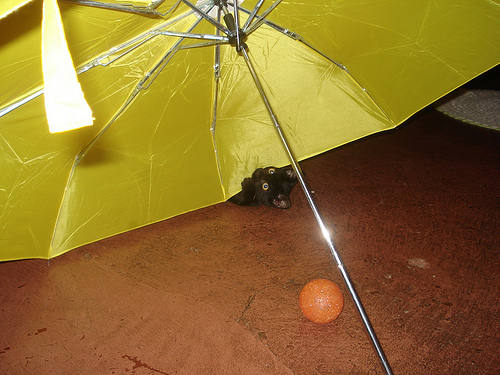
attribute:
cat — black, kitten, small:
[232, 162, 305, 211]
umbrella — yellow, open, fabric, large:
[1, 1, 499, 264]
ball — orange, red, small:
[294, 274, 348, 326]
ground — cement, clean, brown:
[4, 113, 500, 373]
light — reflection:
[312, 216, 345, 250]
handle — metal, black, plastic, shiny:
[242, 43, 389, 371]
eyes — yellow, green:
[264, 160, 278, 196]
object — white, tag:
[33, 1, 102, 136]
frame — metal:
[1, 7, 362, 148]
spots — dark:
[4, 320, 164, 373]